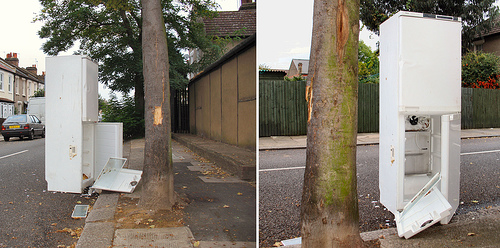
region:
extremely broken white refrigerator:
[373, 8, 470, 238]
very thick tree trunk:
[296, 0, 368, 246]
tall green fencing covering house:
[257, 75, 306, 137]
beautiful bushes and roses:
[463, 45, 498, 99]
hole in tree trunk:
[328, 3, 355, 67]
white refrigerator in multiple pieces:
[42, 53, 147, 225]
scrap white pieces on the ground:
[65, 150, 150, 223]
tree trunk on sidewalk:
[131, 2, 186, 240]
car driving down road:
[0, 108, 45, 144]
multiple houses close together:
[0, 55, 44, 114]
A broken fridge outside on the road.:
[36, 51, 141, 196]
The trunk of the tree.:
[131, 14, 188, 212]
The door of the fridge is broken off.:
[377, 103, 469, 233]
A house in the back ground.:
[182, 5, 259, 152]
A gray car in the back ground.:
[1, 109, 45, 142]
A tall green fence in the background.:
[262, 77, 307, 142]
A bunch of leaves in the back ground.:
[47, 11, 125, 50]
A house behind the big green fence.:
[277, 56, 309, 83]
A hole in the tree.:
[330, 4, 353, 61]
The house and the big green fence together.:
[261, 49, 313, 145]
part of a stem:
[333, 105, 348, 146]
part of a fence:
[283, 90, 288, 99]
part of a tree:
[329, 177, 337, 189]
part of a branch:
[114, 45, 121, 55]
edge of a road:
[91, 215, 93, 242]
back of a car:
[9, 113, 19, 128]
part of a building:
[14, 63, 22, 74]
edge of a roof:
[218, 29, 223, 41]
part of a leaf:
[182, 10, 203, 31]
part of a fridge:
[73, 120, 75, 130]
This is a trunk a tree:
[139, 2, 191, 217]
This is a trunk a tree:
[300, 2, 381, 243]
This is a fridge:
[374, 4, 487, 244]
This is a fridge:
[33, 52, 132, 207]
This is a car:
[5, 105, 52, 147]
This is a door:
[215, 49, 238, 144]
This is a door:
[235, 56, 257, 149]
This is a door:
[206, 71, 223, 147]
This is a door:
[191, 76, 209, 145]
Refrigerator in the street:
[35, 55, 145, 195]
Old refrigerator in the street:
[40, 50, 145, 195]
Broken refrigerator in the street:
[40, 50, 140, 195]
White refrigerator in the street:
[40, 50, 145, 195]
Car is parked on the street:
[0, 114, 47, 141]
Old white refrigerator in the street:
[40, 51, 145, 192]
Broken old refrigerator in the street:
[40, 51, 145, 194]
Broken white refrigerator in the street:
[40, 50, 145, 190]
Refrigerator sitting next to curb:
[40, 50, 145, 192]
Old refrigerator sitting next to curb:
[41, 52, 146, 195]